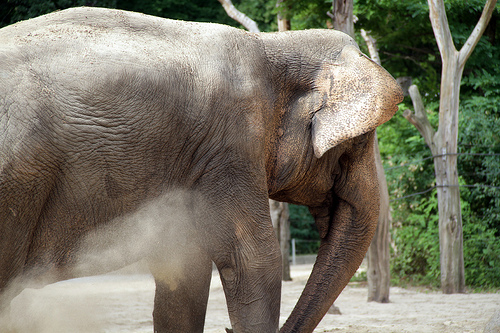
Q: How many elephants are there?
A: One.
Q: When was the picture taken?
A: Daytime.